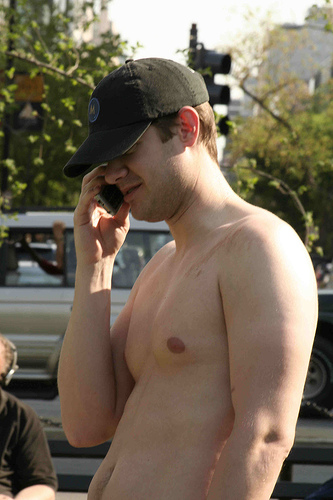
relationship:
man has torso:
[62, 57, 321, 498] [139, 267, 238, 460]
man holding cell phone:
[62, 57, 321, 498] [95, 188, 120, 211]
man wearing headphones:
[6, 345, 44, 499] [6, 365, 18, 389]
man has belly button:
[62, 57, 321, 498] [104, 463, 116, 484]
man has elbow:
[62, 57, 321, 498] [268, 430, 293, 458]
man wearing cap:
[62, 57, 321, 498] [88, 72, 195, 116]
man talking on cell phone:
[62, 57, 321, 498] [95, 188, 120, 211]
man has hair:
[62, 57, 321, 498] [203, 110, 217, 139]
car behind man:
[6, 222, 58, 347] [6, 345, 44, 499]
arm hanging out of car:
[54, 226, 66, 262] [6, 222, 58, 347]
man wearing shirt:
[6, 345, 44, 499] [3, 404, 19, 420]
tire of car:
[311, 349, 330, 415] [6, 222, 58, 347]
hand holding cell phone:
[74, 210, 126, 257] [95, 188, 120, 211]